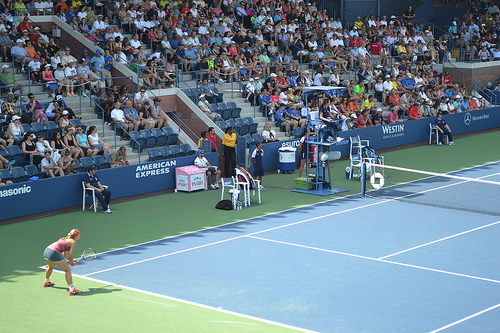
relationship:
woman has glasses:
[21, 130, 40, 157] [25, 132, 35, 139]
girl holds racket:
[43, 228, 81, 295] [77, 248, 97, 263]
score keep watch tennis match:
[81, 165, 115, 217] [21, 213, 111, 307]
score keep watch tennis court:
[430, 105, 459, 148] [66, 160, 498, 330]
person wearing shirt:
[219, 127, 239, 179] [222, 132, 238, 146]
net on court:
[362, 161, 499, 219] [37, 130, 498, 327]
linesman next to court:
[319, 94, 339, 137] [40, 159, 484, 324]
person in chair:
[80, 163, 114, 213] [81, 179, 103, 215]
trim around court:
[7, 121, 484, 320] [40, 159, 484, 324]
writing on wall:
[133, 155, 177, 183] [3, 102, 484, 230]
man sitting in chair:
[434, 114, 450, 136] [423, 101, 449, 141]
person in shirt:
[219, 129, 238, 153] [218, 132, 231, 142]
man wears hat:
[87, 162, 118, 217] [88, 162, 98, 171]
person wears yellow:
[222, 127, 238, 178] [220, 130, 236, 145]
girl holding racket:
[43, 228, 81, 295] [72, 245, 96, 268]